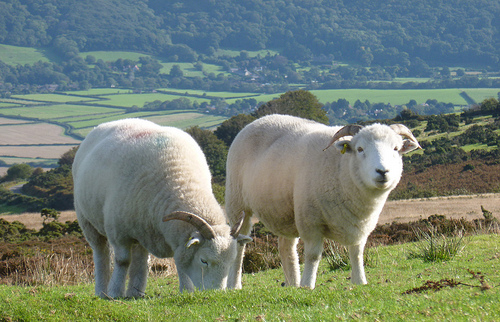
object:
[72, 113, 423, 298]
sheep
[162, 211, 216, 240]
horns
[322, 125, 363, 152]
horns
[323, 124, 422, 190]
head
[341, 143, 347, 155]
tag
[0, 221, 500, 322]
grass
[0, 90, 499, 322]
hillside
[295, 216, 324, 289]
legs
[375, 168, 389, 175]
nose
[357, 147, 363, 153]
eyes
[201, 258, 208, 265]
eye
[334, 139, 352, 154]
ears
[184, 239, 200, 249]
ears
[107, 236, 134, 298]
legs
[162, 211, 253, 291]
head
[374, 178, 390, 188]
mouth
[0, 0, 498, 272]
trees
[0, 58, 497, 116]
distance